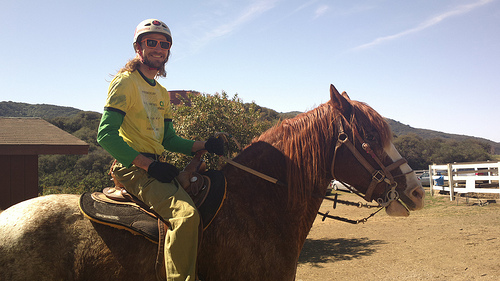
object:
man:
[96, 18, 227, 281]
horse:
[0, 83, 426, 281]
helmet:
[132, 18, 172, 45]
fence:
[428, 160, 500, 202]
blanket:
[78, 168, 228, 281]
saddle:
[102, 148, 205, 230]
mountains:
[0, 100, 500, 197]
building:
[1, 117, 90, 211]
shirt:
[104, 69, 174, 155]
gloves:
[146, 161, 179, 184]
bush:
[164, 88, 271, 171]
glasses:
[141, 38, 171, 50]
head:
[316, 83, 425, 218]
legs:
[114, 163, 202, 281]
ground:
[295, 180, 500, 281]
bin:
[433, 175, 444, 186]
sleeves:
[96, 110, 140, 169]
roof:
[0, 117, 89, 146]